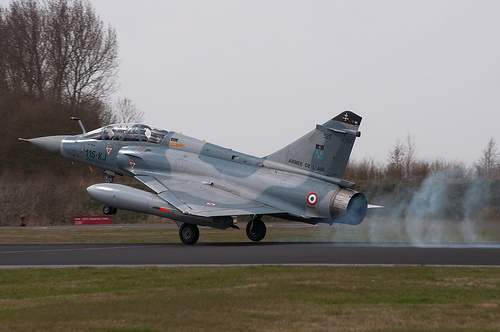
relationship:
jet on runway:
[17, 109, 368, 239] [142, 246, 188, 261]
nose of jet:
[10, 129, 62, 148] [17, 109, 368, 239]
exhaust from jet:
[387, 185, 491, 236] [17, 109, 368, 239]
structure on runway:
[67, 210, 114, 227] [142, 246, 188, 261]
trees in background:
[409, 161, 445, 180] [394, 165, 428, 178]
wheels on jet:
[170, 219, 199, 245] [17, 109, 368, 239]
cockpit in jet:
[85, 120, 151, 142] [17, 109, 368, 239]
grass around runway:
[80, 275, 126, 298] [142, 246, 188, 261]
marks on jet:
[301, 188, 318, 208] [17, 109, 368, 239]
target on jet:
[301, 188, 318, 208] [17, 109, 368, 239]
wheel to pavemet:
[170, 219, 199, 245] [181, 248, 222, 264]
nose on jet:
[10, 129, 62, 148] [17, 109, 368, 239]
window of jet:
[93, 126, 150, 138] [17, 109, 368, 239]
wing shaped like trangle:
[134, 168, 262, 229] [140, 171, 264, 226]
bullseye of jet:
[301, 188, 318, 208] [17, 109, 368, 239]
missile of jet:
[84, 179, 148, 209] [17, 109, 368, 239]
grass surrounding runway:
[80, 275, 126, 298] [142, 246, 188, 261]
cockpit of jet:
[85, 120, 151, 142] [17, 109, 368, 239]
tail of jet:
[274, 103, 359, 168] [17, 109, 368, 239]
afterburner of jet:
[340, 196, 375, 221] [17, 109, 368, 239]